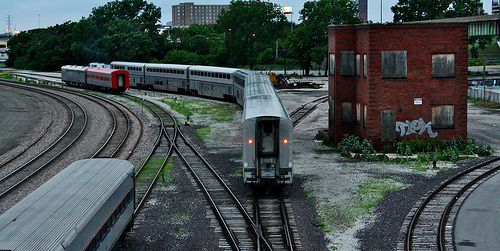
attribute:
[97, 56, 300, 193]
train — red, long, running, gray, silver, on tracks, grey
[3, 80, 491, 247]
tracks — brown, black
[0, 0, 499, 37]
sky — far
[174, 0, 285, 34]
building — behind trees, large, old, abandoned, brown, tall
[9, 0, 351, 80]
trees — green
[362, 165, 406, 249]
gravel — black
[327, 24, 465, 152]
building — red, brick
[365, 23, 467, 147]
wall — red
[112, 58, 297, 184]
train — short, silver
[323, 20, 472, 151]
building — red, brick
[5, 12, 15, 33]
radio tower — tall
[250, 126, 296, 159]
lights — red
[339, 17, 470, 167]
building — brick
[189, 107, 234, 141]
grass — green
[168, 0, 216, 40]
building — grey